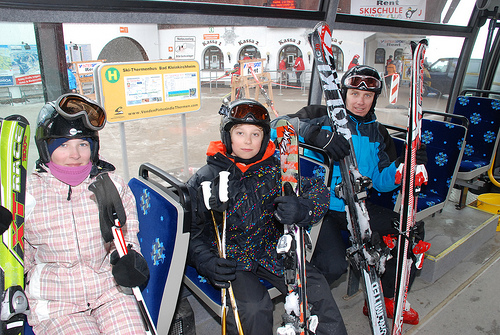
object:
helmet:
[219, 96, 272, 162]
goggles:
[229, 102, 269, 122]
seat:
[118, 159, 195, 333]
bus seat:
[182, 144, 329, 315]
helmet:
[34, 92, 100, 140]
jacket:
[269, 106, 415, 211]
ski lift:
[0, 79, 427, 335]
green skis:
[1, 112, 28, 332]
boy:
[188, 98, 345, 334]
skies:
[269, 112, 321, 333]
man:
[180, 95, 351, 335]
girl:
[2, 88, 148, 335]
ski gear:
[277, 100, 409, 295]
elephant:
[47, 161, 93, 187]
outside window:
[3, 21, 497, 188]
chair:
[384, 109, 468, 218]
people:
[292, 54, 306, 88]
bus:
[0, 1, 496, 335]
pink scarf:
[45, 162, 96, 187]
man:
[270, 62, 426, 325]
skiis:
[394, 35, 428, 332]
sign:
[99, 60, 203, 124]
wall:
[117, 165, 172, 200]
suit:
[10, 154, 156, 335]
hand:
[0, 204, 15, 234]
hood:
[204, 136, 274, 171]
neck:
[37, 162, 97, 185]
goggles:
[56, 93, 108, 130]